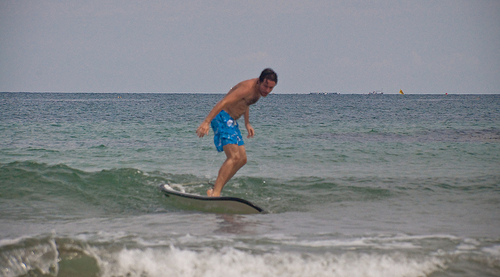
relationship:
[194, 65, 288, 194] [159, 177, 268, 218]
man on surfboard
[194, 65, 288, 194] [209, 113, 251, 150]
man wears shorts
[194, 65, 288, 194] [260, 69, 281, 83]
man has hair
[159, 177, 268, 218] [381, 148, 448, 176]
surfboard on water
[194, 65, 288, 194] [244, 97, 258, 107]
man has chesthair